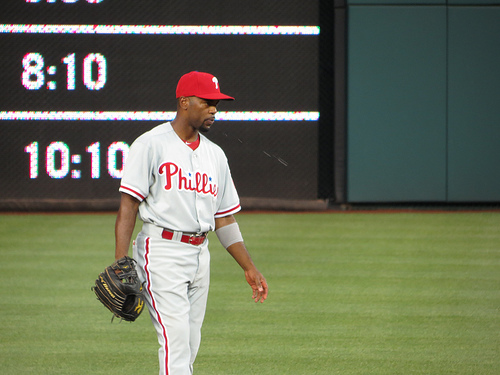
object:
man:
[114, 70, 269, 375]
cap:
[176, 70, 235, 100]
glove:
[90, 255, 145, 323]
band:
[215, 222, 243, 249]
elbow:
[215, 213, 237, 231]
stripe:
[143, 237, 168, 375]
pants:
[132, 222, 209, 375]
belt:
[141, 222, 210, 246]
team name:
[158, 162, 219, 197]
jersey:
[118, 121, 242, 237]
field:
[1, 207, 499, 374]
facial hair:
[198, 116, 215, 132]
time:
[20, 52, 108, 91]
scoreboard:
[1, 0, 350, 211]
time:
[24, 141, 131, 180]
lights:
[0, 0, 320, 180]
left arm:
[214, 175, 258, 269]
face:
[189, 96, 217, 128]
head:
[176, 71, 220, 133]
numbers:
[20, 52, 45, 91]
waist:
[142, 217, 216, 246]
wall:
[345, 0, 499, 202]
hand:
[243, 266, 268, 303]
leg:
[132, 278, 193, 375]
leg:
[188, 246, 211, 375]